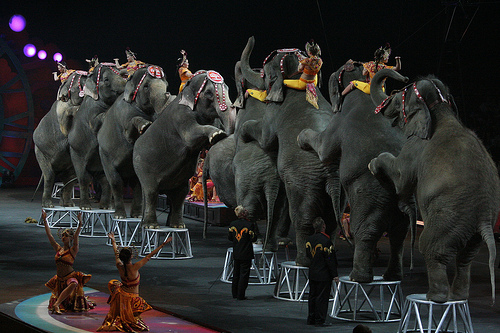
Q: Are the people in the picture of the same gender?
A: Yes, all the people are female.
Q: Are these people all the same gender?
A: Yes, all the people are female.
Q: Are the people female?
A: Yes, all the people are female.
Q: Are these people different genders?
A: No, all the people are female.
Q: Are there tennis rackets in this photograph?
A: No, there are no tennis rackets.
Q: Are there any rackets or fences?
A: No, there are no rackets or fences.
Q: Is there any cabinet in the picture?
A: No, there are no cabinets.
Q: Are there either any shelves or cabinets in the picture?
A: No, there are no cabinets or shelves.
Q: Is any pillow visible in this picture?
A: No, there are no pillows.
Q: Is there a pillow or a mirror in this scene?
A: No, there are no pillows or mirrors.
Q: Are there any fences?
A: No, there are no fences.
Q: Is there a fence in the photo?
A: No, there are no fences.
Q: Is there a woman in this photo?
A: Yes, there is a woman.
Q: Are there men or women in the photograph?
A: Yes, there is a woman.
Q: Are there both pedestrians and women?
A: No, there is a woman but no pedestrians.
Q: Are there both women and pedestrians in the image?
A: No, there is a woman but no pedestrians.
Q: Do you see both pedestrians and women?
A: No, there is a woman but no pedestrians.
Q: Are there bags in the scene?
A: No, there are no bags.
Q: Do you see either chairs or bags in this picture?
A: No, there are no bags or chairs.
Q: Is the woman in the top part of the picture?
A: Yes, the woman is in the top of the image.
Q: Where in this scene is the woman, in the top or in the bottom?
A: The woman is in the top of the image.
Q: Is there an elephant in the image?
A: Yes, there is an elephant.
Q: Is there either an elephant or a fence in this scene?
A: Yes, there is an elephant.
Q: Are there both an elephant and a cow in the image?
A: No, there is an elephant but no cows.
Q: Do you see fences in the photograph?
A: No, there are no fences.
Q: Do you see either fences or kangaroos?
A: No, there are no fences or kangaroos.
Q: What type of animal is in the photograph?
A: The animal is an elephant.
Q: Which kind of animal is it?
A: The animal is an elephant.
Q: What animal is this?
A: That is an elephant.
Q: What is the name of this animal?
A: That is an elephant.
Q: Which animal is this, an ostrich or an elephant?
A: That is an elephant.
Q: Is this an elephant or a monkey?
A: This is an elephant.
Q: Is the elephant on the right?
A: Yes, the elephant is on the right of the image.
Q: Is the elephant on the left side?
A: No, the elephant is on the right of the image.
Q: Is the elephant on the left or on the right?
A: The elephant is on the right of the image.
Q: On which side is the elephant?
A: The elephant is on the right of the image.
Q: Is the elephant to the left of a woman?
A: No, the elephant is to the right of a woman.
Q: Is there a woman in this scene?
A: Yes, there is a woman.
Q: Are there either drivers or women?
A: Yes, there is a woman.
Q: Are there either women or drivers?
A: Yes, there is a woman.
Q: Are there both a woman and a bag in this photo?
A: No, there is a woman but no bags.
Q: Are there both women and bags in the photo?
A: No, there is a woman but no bags.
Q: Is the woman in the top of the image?
A: Yes, the woman is in the top of the image.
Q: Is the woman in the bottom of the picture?
A: No, the woman is in the top of the image.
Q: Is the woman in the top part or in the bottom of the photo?
A: The woman is in the top of the image.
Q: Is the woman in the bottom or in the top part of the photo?
A: The woman is in the top of the image.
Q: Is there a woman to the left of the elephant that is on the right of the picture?
A: Yes, there is a woman to the left of the elephant.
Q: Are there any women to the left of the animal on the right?
A: Yes, there is a woman to the left of the elephant.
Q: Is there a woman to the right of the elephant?
A: No, the woman is to the left of the elephant.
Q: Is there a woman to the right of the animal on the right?
A: No, the woman is to the left of the elephant.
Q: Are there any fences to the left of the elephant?
A: No, there is a woman to the left of the elephant.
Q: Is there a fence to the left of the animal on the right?
A: No, there is a woman to the left of the elephant.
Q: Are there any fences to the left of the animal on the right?
A: No, there is a woman to the left of the elephant.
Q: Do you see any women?
A: Yes, there is a woman.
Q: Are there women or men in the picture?
A: Yes, there is a woman.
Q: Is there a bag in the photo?
A: No, there are no bags.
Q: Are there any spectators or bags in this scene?
A: No, there are no bags or spectators.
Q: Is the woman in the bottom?
A: No, the woman is in the top of the image.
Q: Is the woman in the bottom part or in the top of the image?
A: The woman is in the top of the image.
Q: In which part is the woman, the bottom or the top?
A: The woman is in the top of the image.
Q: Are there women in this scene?
A: Yes, there is a woman.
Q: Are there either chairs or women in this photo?
A: Yes, there is a woman.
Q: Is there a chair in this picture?
A: No, there are no chairs.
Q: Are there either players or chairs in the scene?
A: No, there are no chairs or players.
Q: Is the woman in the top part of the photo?
A: Yes, the woman is in the top of the image.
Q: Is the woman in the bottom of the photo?
A: No, the woman is in the top of the image.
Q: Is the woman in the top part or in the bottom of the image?
A: The woman is in the top of the image.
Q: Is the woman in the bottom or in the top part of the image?
A: The woman is in the top of the image.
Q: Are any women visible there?
A: Yes, there is a woman.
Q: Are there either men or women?
A: Yes, there is a woman.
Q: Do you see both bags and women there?
A: No, there is a woman but no bags.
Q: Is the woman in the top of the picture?
A: Yes, the woman is in the top of the image.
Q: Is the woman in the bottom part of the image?
A: No, the woman is in the top of the image.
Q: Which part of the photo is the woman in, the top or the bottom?
A: The woman is in the top of the image.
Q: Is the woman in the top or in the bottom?
A: The woman is in the top of the image.